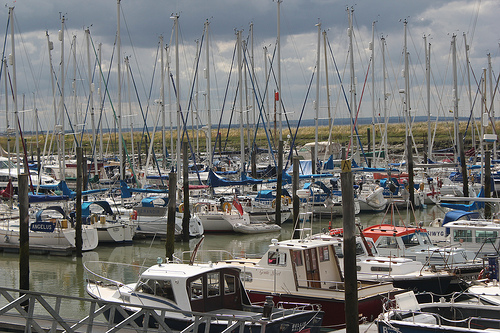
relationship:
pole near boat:
[75, 146, 84, 256] [1, 206, 99, 253]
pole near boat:
[166, 170, 177, 257] [1, 206, 99, 253]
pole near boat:
[182, 140, 191, 243] [125, 194, 205, 241]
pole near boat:
[275, 139, 284, 223] [223, 188, 293, 223]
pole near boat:
[16, 172, 32, 312] [78, 255, 323, 332]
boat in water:
[1, 206, 99, 253] [4, 197, 473, 323]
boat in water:
[125, 194, 205, 241] [4, 197, 473, 323]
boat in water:
[223, 188, 293, 223] [4, 197, 473, 323]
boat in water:
[78, 255, 323, 332] [4, 197, 473, 323]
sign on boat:
[30, 220, 55, 231] [1, 206, 99, 253]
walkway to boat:
[1, 282, 271, 331] [78, 255, 323, 332]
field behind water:
[2, 119, 499, 150] [4, 197, 473, 323]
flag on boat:
[232, 198, 243, 216] [223, 188, 293, 224]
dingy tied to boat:
[231, 219, 283, 236] [223, 188, 293, 224]